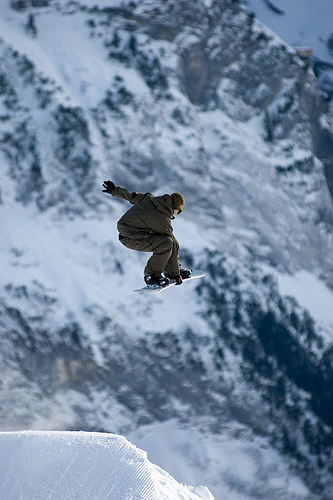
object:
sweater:
[111, 187, 181, 276]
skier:
[101, 179, 193, 290]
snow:
[0, 4, 330, 500]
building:
[227, 394, 249, 427]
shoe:
[143, 270, 170, 288]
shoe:
[164, 266, 193, 280]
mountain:
[0, 0, 331, 499]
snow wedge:
[0, 428, 120, 435]